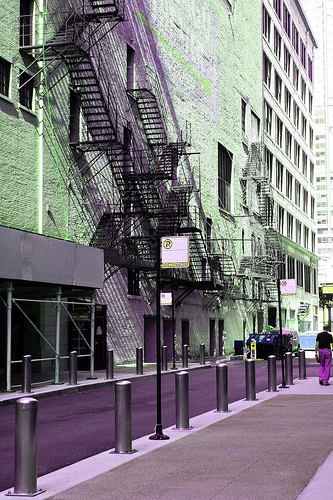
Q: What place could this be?
A: It is a sidewalk.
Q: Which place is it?
A: It is a sidewalk.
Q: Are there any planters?
A: No, there are no planters.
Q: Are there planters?
A: No, there are no planters.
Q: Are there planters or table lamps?
A: No, there are no planters or table lamps.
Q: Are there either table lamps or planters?
A: No, there are no planters or table lamps.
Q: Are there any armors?
A: No, there are no armors.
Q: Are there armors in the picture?
A: No, there are no armors.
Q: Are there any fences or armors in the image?
A: No, there are no armors or fences.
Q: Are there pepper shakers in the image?
A: No, there are no pepper shakers.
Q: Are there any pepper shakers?
A: No, there are no pepper shakers.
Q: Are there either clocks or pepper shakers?
A: No, there are no pepper shakers or clocks.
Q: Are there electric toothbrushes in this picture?
A: No, there are no electric toothbrushes.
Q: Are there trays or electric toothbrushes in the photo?
A: No, there are no electric toothbrushes or trays.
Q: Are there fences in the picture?
A: No, there are no fences.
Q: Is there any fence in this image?
A: No, there are no fences.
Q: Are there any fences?
A: No, there are no fences.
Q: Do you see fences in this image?
A: No, there are no fences.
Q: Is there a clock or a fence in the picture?
A: No, there are no fences or clocks.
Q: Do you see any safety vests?
A: No, there are no safety vests.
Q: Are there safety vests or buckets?
A: No, there are no safety vests or buckets.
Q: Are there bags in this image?
A: No, there are no bags.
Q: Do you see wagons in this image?
A: No, there are no wagons.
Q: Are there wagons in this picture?
A: No, there are no wagons.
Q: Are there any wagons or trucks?
A: No, there are no wagons or trucks.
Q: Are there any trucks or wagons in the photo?
A: No, there are no wagons or trucks.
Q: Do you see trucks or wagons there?
A: No, there are no wagons or trucks.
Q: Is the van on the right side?
A: Yes, the van is on the right of the image.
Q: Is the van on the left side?
A: No, the van is on the right of the image.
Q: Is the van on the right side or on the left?
A: The van is on the right of the image.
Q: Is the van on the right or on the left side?
A: The van is on the right of the image.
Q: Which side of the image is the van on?
A: The van is on the right of the image.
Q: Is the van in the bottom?
A: Yes, the van is in the bottom of the image.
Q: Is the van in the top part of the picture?
A: No, the van is in the bottom of the image.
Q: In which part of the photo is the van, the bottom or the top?
A: The van is in the bottom of the image.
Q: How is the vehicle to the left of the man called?
A: The vehicle is a van.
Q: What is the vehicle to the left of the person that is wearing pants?
A: The vehicle is a van.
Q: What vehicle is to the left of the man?
A: The vehicle is a van.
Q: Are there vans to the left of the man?
A: Yes, there is a van to the left of the man.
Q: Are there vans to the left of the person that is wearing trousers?
A: Yes, there is a van to the left of the man.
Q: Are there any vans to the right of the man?
A: No, the van is to the left of the man.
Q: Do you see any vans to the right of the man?
A: No, the van is to the left of the man.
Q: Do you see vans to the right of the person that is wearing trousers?
A: No, the van is to the left of the man.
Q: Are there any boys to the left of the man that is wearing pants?
A: No, there is a van to the left of the man.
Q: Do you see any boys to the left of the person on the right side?
A: No, there is a van to the left of the man.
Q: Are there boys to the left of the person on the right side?
A: No, there is a van to the left of the man.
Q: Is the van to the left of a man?
A: Yes, the van is to the left of a man.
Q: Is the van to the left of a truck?
A: No, the van is to the left of a man.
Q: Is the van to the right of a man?
A: No, the van is to the left of a man.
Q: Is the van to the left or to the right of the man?
A: The van is to the left of the man.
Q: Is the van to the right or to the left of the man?
A: The van is to the left of the man.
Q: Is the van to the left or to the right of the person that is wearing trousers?
A: The van is to the left of the man.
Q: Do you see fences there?
A: No, there are no fences.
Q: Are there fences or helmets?
A: No, there are no fences or helmets.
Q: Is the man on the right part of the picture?
A: Yes, the man is on the right of the image.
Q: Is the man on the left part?
A: No, the man is on the right of the image.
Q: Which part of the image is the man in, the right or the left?
A: The man is on the right of the image.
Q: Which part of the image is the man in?
A: The man is on the right of the image.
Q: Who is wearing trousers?
A: The man is wearing trousers.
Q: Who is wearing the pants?
A: The man is wearing trousers.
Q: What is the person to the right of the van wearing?
A: The man is wearing trousers.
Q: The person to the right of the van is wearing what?
A: The man is wearing trousers.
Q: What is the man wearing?
A: The man is wearing trousers.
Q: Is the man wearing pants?
A: Yes, the man is wearing pants.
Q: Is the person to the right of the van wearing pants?
A: Yes, the man is wearing pants.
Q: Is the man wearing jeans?
A: No, the man is wearing pants.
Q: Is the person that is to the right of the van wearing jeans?
A: No, the man is wearing pants.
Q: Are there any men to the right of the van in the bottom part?
A: Yes, there is a man to the right of the van.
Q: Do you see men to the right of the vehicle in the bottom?
A: Yes, there is a man to the right of the van.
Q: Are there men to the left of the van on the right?
A: No, the man is to the right of the van.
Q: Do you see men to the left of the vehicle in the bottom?
A: No, the man is to the right of the van.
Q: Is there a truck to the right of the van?
A: No, there is a man to the right of the van.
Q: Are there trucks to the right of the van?
A: No, there is a man to the right of the van.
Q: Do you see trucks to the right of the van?
A: No, there is a man to the right of the van.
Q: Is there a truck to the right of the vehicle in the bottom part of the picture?
A: No, there is a man to the right of the van.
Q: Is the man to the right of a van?
A: Yes, the man is to the right of a van.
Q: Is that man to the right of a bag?
A: No, the man is to the right of a van.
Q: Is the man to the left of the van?
A: No, the man is to the right of the van.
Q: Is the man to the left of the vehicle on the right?
A: No, the man is to the right of the van.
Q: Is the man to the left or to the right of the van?
A: The man is to the right of the van.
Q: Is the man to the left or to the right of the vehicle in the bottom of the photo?
A: The man is to the right of the van.